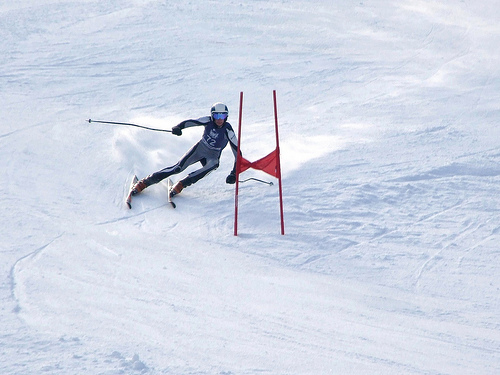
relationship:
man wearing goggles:
[134, 103, 243, 203] [210, 111, 228, 119]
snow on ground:
[0, 0, 500, 375] [0, 229, 499, 372]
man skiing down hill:
[134, 103, 243, 203] [0, 2, 498, 374]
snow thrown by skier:
[68, 100, 188, 204] [141, 89, 281, 207]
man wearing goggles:
[134, 103, 243, 203] [211, 112, 228, 119]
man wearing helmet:
[134, 103, 243, 203] [209, 102, 230, 130]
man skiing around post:
[134, 103, 243, 203] [232, 89, 247, 237]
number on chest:
[206, 134, 216, 146] [196, 116, 229, 151]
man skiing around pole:
[134, 103, 243, 203] [229, 64, 264, 246]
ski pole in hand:
[85, 116, 176, 137] [170, 125, 184, 138]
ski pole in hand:
[235, 176, 275, 190] [225, 170, 237, 184]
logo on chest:
[207, 127, 222, 143] [198, 117, 235, 153]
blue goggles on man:
[210, 109, 230, 120] [134, 103, 243, 203]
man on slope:
[134, 103, 243, 203] [6, 5, 484, 367]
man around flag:
[134, 103, 243, 203] [239, 147, 278, 177]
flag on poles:
[239, 147, 278, 177] [230, 88, 286, 236]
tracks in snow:
[285, 204, 477, 271] [4, 3, 484, 369]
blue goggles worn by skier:
[211, 112, 229, 120] [171, 104, 262, 179]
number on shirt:
[204, 132, 216, 147] [174, 116, 240, 150]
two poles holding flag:
[210, 84, 341, 259] [238, 145, 279, 175]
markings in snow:
[3, 192, 210, 344] [1, 175, 498, 371]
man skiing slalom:
[93, 81, 264, 260] [5, 6, 484, 366]